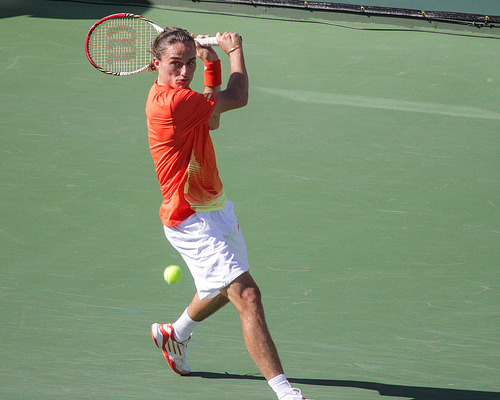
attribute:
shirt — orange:
[132, 79, 228, 228]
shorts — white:
[148, 188, 273, 337]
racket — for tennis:
[65, 16, 179, 96]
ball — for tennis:
[144, 252, 225, 308]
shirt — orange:
[132, 82, 231, 215]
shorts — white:
[169, 211, 236, 308]